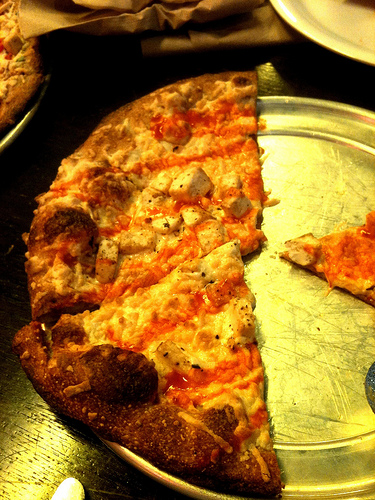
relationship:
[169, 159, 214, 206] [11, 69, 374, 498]
chicken on pizza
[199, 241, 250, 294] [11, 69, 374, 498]
chicken on pizza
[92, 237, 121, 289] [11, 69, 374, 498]
chicken on pizza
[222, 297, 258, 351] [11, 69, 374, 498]
chicken on pizza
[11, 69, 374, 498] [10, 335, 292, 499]
pizza has crust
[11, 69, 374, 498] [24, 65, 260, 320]
pizza has crust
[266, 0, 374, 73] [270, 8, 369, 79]
pizza pan has edge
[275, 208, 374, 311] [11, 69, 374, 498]
slice off pizza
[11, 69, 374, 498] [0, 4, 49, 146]
pizza close to pizza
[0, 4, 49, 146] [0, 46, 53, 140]
pizza has edge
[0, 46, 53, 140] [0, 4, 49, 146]
edge on pizza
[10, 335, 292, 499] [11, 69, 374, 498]
crust on pizza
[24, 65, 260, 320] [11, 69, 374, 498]
crust on pizza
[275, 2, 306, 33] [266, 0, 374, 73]
reflection in pizza pan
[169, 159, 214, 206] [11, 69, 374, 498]
chicken on top of pizza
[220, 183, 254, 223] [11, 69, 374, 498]
chicken on top of pizza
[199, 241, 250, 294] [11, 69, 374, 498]
chicken on top of pizza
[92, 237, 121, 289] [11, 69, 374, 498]
chicken on top of pizza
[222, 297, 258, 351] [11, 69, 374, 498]
chicken on top of pizza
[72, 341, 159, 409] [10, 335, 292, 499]
air bubble in crust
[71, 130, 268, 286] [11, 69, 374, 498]
cheese on top of pizza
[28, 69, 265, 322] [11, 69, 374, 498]
cheese on top of pizza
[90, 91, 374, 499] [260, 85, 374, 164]
pizza tray has edge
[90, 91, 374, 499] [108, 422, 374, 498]
pizza tray has edge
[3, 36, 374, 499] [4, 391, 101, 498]
table has wear and tear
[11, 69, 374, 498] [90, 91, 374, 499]
pizza on pizza tray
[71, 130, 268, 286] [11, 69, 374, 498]
cheese on pizza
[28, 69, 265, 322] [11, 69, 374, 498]
cheese on pizza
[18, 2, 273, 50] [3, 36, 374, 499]
napkin on table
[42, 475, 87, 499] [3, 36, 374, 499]
knife on table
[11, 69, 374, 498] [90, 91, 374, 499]
pizza on top of pizza tray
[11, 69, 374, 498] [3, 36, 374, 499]
pizza on top of table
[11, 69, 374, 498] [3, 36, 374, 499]
pizza on table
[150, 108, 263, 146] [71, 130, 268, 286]
sauce under cheese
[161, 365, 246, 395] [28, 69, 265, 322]
sauce under cheese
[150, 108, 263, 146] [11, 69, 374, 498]
sauce on pizza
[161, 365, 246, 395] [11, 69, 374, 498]
sauce on pizza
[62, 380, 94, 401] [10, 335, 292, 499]
cheese on crust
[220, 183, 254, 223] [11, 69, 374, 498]
chicken on pizza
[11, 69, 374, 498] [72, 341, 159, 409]
pizza has air bubble